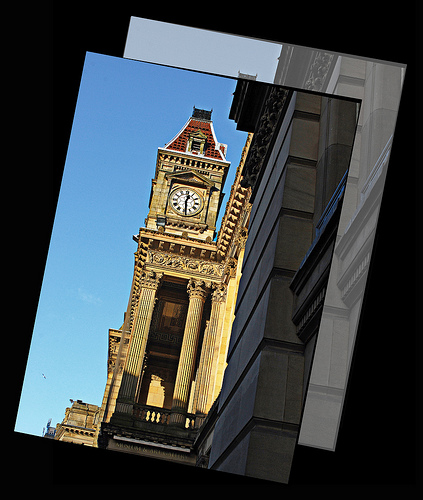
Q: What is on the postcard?
A: Clock.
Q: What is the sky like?
A: Clear.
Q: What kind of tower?
A: Ornate.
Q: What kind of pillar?
A: Stone.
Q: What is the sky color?
A: Blue.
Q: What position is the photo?
A: Tilted.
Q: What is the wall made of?
A: Stone.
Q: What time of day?
A: Afternoon.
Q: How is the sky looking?
A: Clear and blue.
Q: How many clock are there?
A: 1.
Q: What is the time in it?
A: 12:30.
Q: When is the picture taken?
A: Daytime.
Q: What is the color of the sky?
A: Blue.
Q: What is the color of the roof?
A: Red.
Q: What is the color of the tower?
A: Brown.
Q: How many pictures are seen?
A: 2.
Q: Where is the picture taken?
A: Near a mirror.